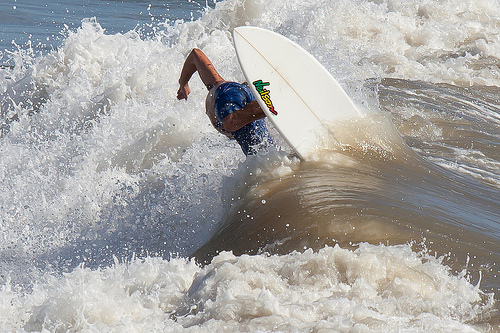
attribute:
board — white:
[228, 14, 377, 167]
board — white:
[232, 22, 365, 159]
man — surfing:
[174, 47, 278, 161]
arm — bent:
[175, 45, 223, 103]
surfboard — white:
[253, 42, 322, 120]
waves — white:
[45, 65, 165, 231]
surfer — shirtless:
[177, 49, 274, 157]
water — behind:
[51, 127, 496, 265]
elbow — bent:
[179, 41, 213, 73]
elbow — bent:
[172, 37, 213, 99]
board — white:
[222, 16, 392, 186]